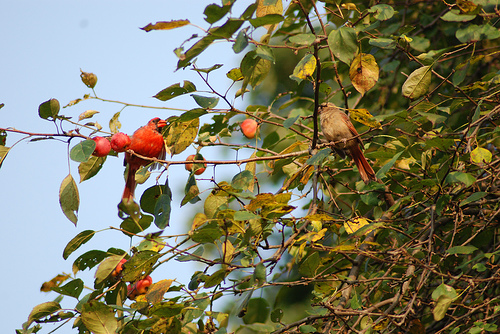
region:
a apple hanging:
[103, 114, 205, 217]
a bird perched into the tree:
[295, 97, 474, 227]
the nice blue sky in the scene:
[15, 22, 80, 81]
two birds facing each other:
[63, 98, 417, 184]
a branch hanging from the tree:
[182, 136, 320, 178]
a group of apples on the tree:
[105, 268, 182, 313]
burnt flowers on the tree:
[374, 92, 441, 205]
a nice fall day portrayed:
[36, 33, 466, 248]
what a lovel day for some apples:
[116, 42, 428, 317]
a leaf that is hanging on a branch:
[34, 105, 73, 127]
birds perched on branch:
[87, 78, 424, 229]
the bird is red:
[108, 100, 178, 219]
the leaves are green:
[150, 72, 273, 324]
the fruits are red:
[70, 117, 137, 168]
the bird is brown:
[301, 96, 390, 204]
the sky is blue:
[19, 26, 133, 97]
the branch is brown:
[203, 142, 350, 200]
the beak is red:
[149, 116, 171, 132]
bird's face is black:
[144, 113, 169, 134]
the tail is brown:
[336, 139, 411, 211]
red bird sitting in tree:
[125, 113, 170, 166]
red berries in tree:
[96, 126, 118, 152]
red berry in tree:
[236, 115, 261, 142]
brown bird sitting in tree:
[306, 100, 378, 183]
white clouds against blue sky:
[11, 7, 131, 59]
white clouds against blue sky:
[8, 174, 43, 283]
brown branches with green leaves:
[318, 207, 484, 310]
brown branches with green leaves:
[46, 297, 208, 330]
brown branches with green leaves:
[365, 14, 490, 150]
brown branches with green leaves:
[171, 13, 308, 84]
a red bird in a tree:
[66, 80, 207, 210]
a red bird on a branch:
[124, 99, 184, 199]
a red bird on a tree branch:
[125, 85, 168, 207]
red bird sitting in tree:
[108, 100, 164, 220]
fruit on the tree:
[39, 107, 158, 188]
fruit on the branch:
[41, 107, 149, 188]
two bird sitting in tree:
[43, 56, 375, 264]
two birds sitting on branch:
[111, 77, 486, 227]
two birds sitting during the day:
[7, 43, 493, 252]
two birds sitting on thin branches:
[62, 41, 473, 206]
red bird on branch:
[108, 122, 202, 214]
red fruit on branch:
[83, 119, 130, 176]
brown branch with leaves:
[77, 122, 299, 171]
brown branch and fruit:
[29, 125, 301, 179]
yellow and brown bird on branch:
[287, 91, 387, 168]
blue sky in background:
[20, 19, 285, 176]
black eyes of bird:
[152, 114, 167, 124]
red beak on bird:
[141, 111, 174, 126]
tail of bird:
[112, 159, 152, 206]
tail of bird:
[337, 149, 386, 187]